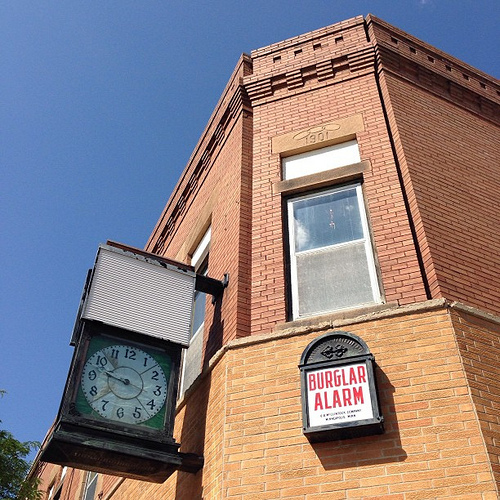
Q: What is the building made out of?
A: Brick.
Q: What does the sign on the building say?
A: BURGLAR ALARM.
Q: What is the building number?
A: 1901.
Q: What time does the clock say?
A: 9:47.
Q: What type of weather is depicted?
A: Sunner and clear.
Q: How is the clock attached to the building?
A: Metal brackets.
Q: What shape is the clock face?
A: Round.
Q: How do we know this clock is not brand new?
A: It's casing is faded and rubbed and the glass is cracked.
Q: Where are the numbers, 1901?
A: Etched on brick, above a window.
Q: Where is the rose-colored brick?
A: On the upper story of an old building.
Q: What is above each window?
A: A recessed, white rectangle and an engraved date.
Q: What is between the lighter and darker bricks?
A: A grey ledge.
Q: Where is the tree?
A: On the left, on the same side as the clock.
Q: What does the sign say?
A: Burglar Alarm.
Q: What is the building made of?
A: Bricks.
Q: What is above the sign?
A: A window.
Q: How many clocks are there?
A: One.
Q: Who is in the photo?
A: Nobody.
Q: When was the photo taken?
A: Daytime.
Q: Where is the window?
A: Above the sign.